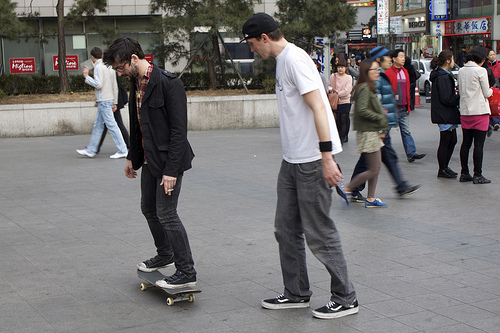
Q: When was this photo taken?
A: During the daytime.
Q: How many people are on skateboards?
A: One.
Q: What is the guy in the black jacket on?
A: A skateboard.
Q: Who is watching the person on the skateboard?
A: A guy in a white shirt.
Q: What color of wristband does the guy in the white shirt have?
A: Black.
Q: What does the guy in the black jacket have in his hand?
A: Cigarette.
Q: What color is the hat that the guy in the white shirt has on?
A: Black.